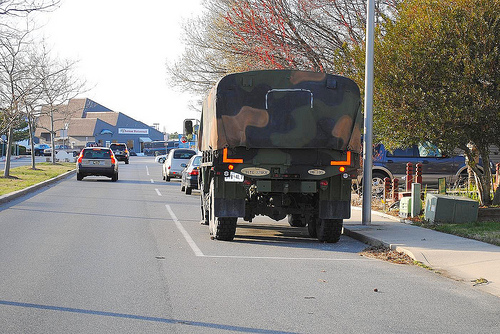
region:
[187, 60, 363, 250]
A military truck is on the road.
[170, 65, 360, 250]
The military truck is on the right side of the road.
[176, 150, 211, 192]
There is a car in front of the military truck.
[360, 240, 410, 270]
There is a pile of leaves in the gutter.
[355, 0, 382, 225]
There is a metal pole beside the rear of the truck.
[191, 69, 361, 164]
The military truck has a camoflauged tarp on it.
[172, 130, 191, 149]
There is a stop sign further down the street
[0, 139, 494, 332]
The street is dry.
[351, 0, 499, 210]
The leaves on the tree are green.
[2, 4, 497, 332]
The picture was taken in the daytime.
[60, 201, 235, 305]
Gray paved road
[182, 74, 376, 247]
Back of a green and brown truck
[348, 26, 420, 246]
Silver pole next to a road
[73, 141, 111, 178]
Back of a tan car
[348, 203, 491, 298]
Gray sidewalk next to a road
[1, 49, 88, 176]
Trees in the middle of a road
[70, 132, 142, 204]
Two cars driving on a road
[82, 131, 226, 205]
Four cars driving on a road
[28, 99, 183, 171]
Building next to a road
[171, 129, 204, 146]
Stop sign by a road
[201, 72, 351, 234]
this is an army truck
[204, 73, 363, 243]
the army truck is moving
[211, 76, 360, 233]
the truck is jungle green in color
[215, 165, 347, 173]
the rare lights are on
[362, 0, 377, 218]
a post is beside the truck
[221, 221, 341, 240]
the truck has large tyres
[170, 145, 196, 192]
vehicles are in front of the truck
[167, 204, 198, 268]
the road has white strip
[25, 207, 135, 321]
the road is clean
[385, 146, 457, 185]
a vehicle is parked beside the road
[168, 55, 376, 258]
a large military truck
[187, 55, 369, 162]
a camo canvas cover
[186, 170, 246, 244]
a few very large tires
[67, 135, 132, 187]
a tan suv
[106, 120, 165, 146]
a white rectangular business sign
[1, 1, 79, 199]
a few trees without leaves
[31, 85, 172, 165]
a brown oddly shaped building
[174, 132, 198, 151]
a red stop sign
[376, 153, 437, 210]
a few red posts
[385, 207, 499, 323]
a driveway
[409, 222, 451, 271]
a sidewalk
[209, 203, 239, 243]
left rear tire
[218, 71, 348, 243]
a big army truck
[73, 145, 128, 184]
a car in the road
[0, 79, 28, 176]
trees of to the side of the road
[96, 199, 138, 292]
the road is gray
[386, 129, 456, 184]
a blue suv is parked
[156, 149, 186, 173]
a white car is parked in the street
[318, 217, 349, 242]
right rear tire of truck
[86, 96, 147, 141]
a building in the background